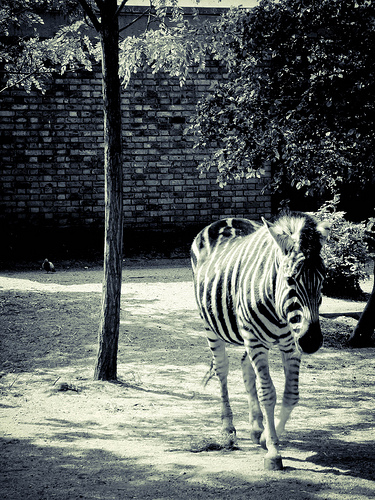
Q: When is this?
A: Daytime.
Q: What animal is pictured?
A: A zebra.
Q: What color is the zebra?
A: Black and white.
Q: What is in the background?
A: A wall.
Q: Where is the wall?
A: Behind the zebra.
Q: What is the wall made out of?
A: Brick.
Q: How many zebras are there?
A: One.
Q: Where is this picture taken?
A: A zoo.